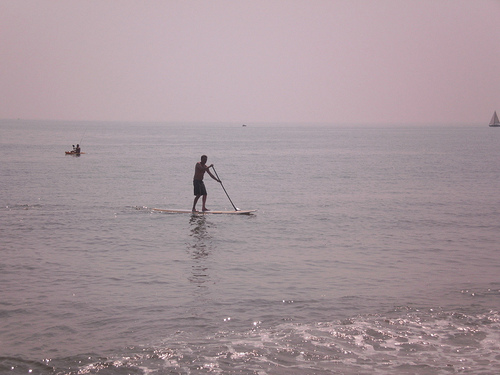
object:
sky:
[0, 0, 499, 129]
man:
[189, 154, 221, 212]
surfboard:
[138, 205, 262, 217]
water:
[1, 122, 499, 373]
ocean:
[0, 119, 499, 369]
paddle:
[211, 165, 240, 212]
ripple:
[14, 311, 499, 374]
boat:
[485, 110, 500, 129]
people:
[65, 141, 84, 157]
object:
[242, 124, 247, 129]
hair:
[200, 153, 206, 161]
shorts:
[192, 179, 208, 197]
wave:
[102, 303, 500, 372]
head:
[199, 154, 211, 167]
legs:
[191, 195, 201, 215]